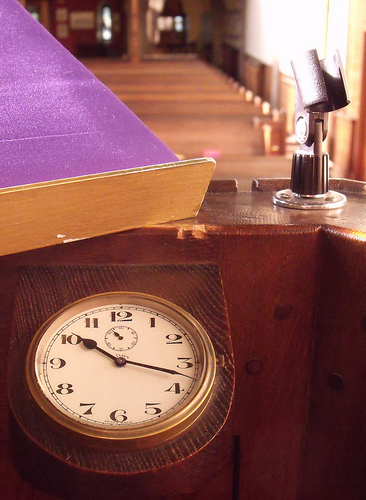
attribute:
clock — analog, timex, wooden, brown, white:
[6, 256, 240, 479]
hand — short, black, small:
[73, 331, 114, 367]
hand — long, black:
[125, 358, 188, 381]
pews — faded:
[72, 46, 295, 157]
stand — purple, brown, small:
[2, 1, 219, 261]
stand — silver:
[274, 110, 354, 214]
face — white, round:
[30, 289, 212, 431]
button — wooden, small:
[271, 302, 297, 323]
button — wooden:
[326, 368, 347, 394]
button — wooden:
[243, 357, 266, 378]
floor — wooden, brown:
[63, 46, 363, 188]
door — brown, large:
[153, 14, 193, 48]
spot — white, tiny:
[51, 232, 68, 240]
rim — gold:
[24, 289, 219, 444]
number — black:
[140, 399, 166, 418]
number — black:
[107, 405, 133, 424]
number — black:
[78, 399, 99, 418]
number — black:
[54, 381, 77, 397]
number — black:
[164, 379, 184, 400]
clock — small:
[102, 325, 142, 353]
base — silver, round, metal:
[273, 189, 351, 210]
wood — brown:
[2, 176, 365, 500]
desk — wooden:
[1, 180, 362, 500]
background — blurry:
[26, 1, 365, 192]